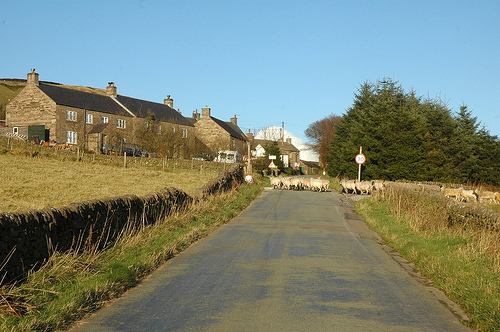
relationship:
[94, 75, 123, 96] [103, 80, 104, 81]
building has chimney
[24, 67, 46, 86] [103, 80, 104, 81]
building has chimney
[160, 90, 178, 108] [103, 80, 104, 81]
building has chimney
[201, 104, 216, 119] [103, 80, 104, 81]
building has chimney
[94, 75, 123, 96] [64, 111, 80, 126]
building has windows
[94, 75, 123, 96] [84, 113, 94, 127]
building has windows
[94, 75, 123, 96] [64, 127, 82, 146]
building has windows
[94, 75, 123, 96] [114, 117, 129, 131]
building has windows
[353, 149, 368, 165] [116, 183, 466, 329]
sign next to road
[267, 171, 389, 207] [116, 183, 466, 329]
cows crossing road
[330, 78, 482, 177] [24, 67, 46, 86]
trees across building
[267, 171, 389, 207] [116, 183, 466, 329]
cows walking road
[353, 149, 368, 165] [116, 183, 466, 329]
sign at end of road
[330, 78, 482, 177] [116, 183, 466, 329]
trees at end of road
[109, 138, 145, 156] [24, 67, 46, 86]
car parked at building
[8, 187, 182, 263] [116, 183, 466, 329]
fence by road